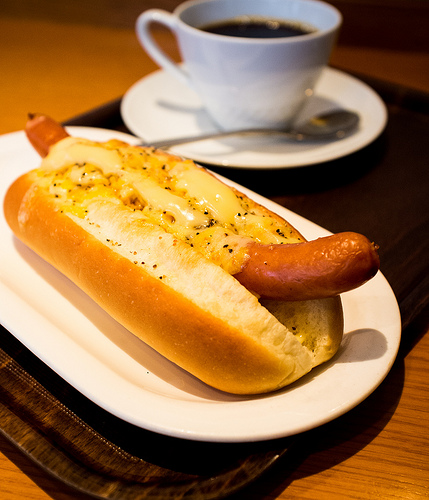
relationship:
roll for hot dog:
[2, 139, 348, 398] [3, 107, 385, 404]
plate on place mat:
[1, 122, 408, 450] [1, 57, 428, 499]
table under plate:
[2, 0, 429, 499] [1, 122, 408, 450]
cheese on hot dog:
[38, 133, 281, 281] [3, 107, 385, 404]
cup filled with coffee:
[132, 0, 343, 147] [193, 13, 320, 42]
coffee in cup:
[193, 13, 320, 42] [132, 0, 343, 147]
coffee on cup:
[193, 13, 320, 42] [132, 0, 343, 147]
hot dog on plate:
[3, 107, 385, 404] [1, 122, 408, 450]